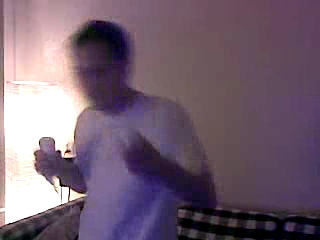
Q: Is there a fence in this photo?
A: No, there are no fences.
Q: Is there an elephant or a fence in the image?
A: No, there are no fences or elephants.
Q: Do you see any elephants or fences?
A: No, there are no fences or elephants.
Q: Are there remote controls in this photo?
A: Yes, there is a remote control.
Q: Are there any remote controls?
A: Yes, there is a remote control.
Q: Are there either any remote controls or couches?
A: Yes, there is a remote control.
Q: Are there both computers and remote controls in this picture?
A: No, there is a remote control but no computers.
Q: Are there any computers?
A: No, there are no computers.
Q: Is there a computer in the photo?
A: No, there are no computers.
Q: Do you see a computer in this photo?
A: No, there are no computers.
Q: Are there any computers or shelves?
A: No, there are no computers or shelves.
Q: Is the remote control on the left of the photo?
A: Yes, the remote control is on the left of the image.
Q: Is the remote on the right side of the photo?
A: No, the remote is on the left of the image.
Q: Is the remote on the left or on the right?
A: The remote is on the left of the image.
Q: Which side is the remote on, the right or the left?
A: The remote is on the left of the image.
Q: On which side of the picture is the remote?
A: The remote is on the left of the image.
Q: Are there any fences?
A: No, there are no fences.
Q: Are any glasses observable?
A: No, there are no glasses.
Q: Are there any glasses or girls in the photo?
A: No, there are no glasses or girls.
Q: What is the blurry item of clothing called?
A: The clothing item is a shirt.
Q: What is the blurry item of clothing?
A: The clothing item is a shirt.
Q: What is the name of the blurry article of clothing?
A: The clothing item is a shirt.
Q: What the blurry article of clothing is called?
A: The clothing item is a shirt.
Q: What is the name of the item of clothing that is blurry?
A: The clothing item is a shirt.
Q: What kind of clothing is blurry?
A: The clothing is a shirt.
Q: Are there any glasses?
A: No, there are no glasses.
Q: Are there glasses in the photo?
A: No, there are no glasses.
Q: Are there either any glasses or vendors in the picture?
A: No, there are no glasses or vendors.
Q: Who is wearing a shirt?
A: The man is wearing a shirt.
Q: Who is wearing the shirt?
A: The man is wearing a shirt.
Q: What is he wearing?
A: The man is wearing a shirt.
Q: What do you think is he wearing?
A: The man is wearing a shirt.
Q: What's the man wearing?
A: The man is wearing a shirt.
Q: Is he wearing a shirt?
A: Yes, the man is wearing a shirt.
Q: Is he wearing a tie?
A: No, the man is wearing a shirt.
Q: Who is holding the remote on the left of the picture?
A: The man is holding the remote control.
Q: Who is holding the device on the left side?
A: The man is holding the remote control.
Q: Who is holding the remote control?
A: The man is holding the remote control.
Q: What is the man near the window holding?
A: The man is holding the remote control.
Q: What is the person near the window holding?
A: The man is holding the remote control.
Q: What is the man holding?
A: The man is holding the remote control.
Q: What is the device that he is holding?
A: The device is a remote control.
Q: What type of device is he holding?
A: The man is holding the remote control.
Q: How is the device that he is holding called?
A: The device is a remote control.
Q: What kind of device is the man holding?
A: The man is holding the remote control.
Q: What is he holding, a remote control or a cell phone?
A: The man is holding a remote control.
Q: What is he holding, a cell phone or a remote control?
A: The man is holding a remote control.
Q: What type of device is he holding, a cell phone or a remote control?
A: The man is holding a remote control.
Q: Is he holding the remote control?
A: Yes, the man is holding the remote control.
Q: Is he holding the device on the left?
A: Yes, the man is holding the remote control.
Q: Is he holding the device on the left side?
A: Yes, the man is holding the remote control.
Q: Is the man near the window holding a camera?
A: No, the man is holding the remote control.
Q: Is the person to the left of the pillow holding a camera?
A: No, the man is holding the remote control.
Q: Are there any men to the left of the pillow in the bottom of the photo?
A: Yes, there is a man to the left of the pillow.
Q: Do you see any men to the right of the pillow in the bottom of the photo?
A: No, the man is to the left of the pillow.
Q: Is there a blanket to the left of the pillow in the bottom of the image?
A: No, there is a man to the left of the pillow.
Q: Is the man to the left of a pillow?
A: Yes, the man is to the left of a pillow.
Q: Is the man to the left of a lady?
A: No, the man is to the left of a pillow.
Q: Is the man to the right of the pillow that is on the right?
A: No, the man is to the left of the pillow.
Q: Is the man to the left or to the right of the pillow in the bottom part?
A: The man is to the left of the pillow.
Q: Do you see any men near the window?
A: Yes, there is a man near the window.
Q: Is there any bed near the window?
A: No, there is a man near the window.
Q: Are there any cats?
A: Yes, there is a cat.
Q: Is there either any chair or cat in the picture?
A: Yes, there is a cat.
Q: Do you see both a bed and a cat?
A: No, there is a cat but no beds.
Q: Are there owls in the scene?
A: No, there are no owls.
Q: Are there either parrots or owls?
A: No, there are no owls or parrots.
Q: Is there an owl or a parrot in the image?
A: No, there are no owls or parrots.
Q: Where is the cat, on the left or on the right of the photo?
A: The cat is on the left of the image.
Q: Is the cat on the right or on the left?
A: The cat is on the left of the image.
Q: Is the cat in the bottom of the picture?
A: Yes, the cat is in the bottom of the image.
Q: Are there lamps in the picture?
A: Yes, there is a lamp.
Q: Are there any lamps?
A: Yes, there is a lamp.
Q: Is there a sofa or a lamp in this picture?
A: Yes, there is a lamp.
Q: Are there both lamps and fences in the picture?
A: No, there is a lamp but no fences.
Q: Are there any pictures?
A: No, there are no pictures.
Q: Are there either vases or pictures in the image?
A: No, there are no pictures or vases.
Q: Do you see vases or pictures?
A: No, there are no pictures or vases.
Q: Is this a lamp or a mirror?
A: This is a lamp.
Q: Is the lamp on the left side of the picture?
A: Yes, the lamp is on the left of the image.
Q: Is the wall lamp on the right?
A: No, the lamp is on the left of the image.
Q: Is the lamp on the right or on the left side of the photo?
A: The lamp is on the left of the image.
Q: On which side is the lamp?
A: The lamp is on the left of the image.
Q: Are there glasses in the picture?
A: No, there are no glasses.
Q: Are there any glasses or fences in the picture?
A: No, there are no glasses or fences.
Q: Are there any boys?
A: No, there are no boys.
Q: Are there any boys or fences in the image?
A: No, there are no boys or fences.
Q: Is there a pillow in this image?
A: Yes, there is a pillow.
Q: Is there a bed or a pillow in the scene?
A: Yes, there is a pillow.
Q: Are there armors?
A: No, there are no armors.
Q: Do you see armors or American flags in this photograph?
A: No, there are no armors or American flags.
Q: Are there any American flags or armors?
A: No, there are no armors or American flags.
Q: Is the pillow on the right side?
A: Yes, the pillow is on the right of the image.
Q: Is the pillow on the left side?
A: No, the pillow is on the right of the image.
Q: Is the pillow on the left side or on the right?
A: The pillow is on the right of the image.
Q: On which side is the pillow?
A: The pillow is on the right of the image.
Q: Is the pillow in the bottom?
A: Yes, the pillow is in the bottom of the image.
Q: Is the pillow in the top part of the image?
A: No, the pillow is in the bottom of the image.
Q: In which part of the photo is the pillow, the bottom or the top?
A: The pillow is in the bottom of the image.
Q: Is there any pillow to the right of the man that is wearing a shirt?
A: Yes, there is a pillow to the right of the man.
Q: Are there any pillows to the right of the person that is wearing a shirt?
A: Yes, there is a pillow to the right of the man.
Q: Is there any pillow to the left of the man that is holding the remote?
A: No, the pillow is to the right of the man.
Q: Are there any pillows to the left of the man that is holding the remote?
A: No, the pillow is to the right of the man.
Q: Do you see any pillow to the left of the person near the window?
A: No, the pillow is to the right of the man.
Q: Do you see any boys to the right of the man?
A: No, there is a pillow to the right of the man.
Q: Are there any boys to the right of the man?
A: No, there is a pillow to the right of the man.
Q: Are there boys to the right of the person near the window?
A: No, there is a pillow to the right of the man.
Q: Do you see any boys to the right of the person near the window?
A: No, there is a pillow to the right of the man.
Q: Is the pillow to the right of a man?
A: Yes, the pillow is to the right of a man.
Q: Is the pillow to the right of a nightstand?
A: No, the pillow is to the right of a man.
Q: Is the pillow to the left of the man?
A: No, the pillow is to the right of the man.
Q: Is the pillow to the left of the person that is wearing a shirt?
A: No, the pillow is to the right of the man.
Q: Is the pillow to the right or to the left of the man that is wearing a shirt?
A: The pillow is to the right of the man.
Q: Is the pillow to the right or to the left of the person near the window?
A: The pillow is to the right of the man.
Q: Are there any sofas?
A: Yes, there is a sofa.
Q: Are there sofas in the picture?
A: Yes, there is a sofa.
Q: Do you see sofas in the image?
A: Yes, there is a sofa.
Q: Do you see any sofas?
A: Yes, there is a sofa.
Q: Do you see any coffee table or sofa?
A: Yes, there is a sofa.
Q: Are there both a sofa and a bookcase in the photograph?
A: No, there is a sofa but no bookcases.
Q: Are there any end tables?
A: No, there are no end tables.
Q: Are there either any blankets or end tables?
A: No, there are no end tables or blankets.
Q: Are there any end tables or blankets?
A: No, there are no end tables or blankets.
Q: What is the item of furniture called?
A: The piece of furniture is a sofa.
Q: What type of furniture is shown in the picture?
A: The furniture is a sofa.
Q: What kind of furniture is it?
A: The piece of furniture is a sofa.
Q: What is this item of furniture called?
A: This is a sofa.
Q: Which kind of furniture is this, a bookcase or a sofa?
A: This is a sofa.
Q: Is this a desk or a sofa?
A: This is a sofa.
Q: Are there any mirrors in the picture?
A: No, there are no mirrors.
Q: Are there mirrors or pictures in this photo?
A: No, there are no mirrors or pictures.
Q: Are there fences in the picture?
A: No, there are no fences.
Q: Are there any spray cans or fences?
A: No, there are no fences or spray cans.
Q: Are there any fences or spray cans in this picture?
A: No, there are no fences or spray cans.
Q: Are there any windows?
A: Yes, there is a window.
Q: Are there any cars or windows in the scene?
A: Yes, there is a window.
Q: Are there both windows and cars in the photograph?
A: No, there is a window but no cars.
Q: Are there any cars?
A: No, there are no cars.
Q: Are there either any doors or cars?
A: No, there are no cars or doors.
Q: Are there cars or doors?
A: No, there are no cars or doors.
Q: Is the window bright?
A: Yes, the window is bright.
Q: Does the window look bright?
A: Yes, the window is bright.